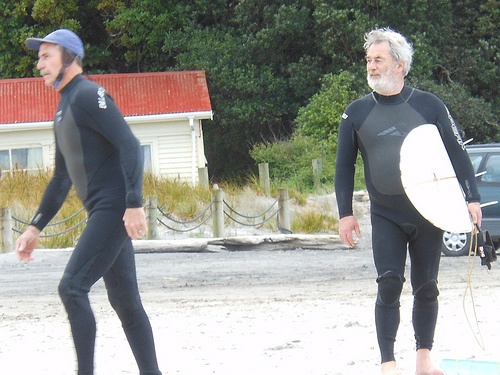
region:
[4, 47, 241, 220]
a white building with a red roof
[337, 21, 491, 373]
a man wearing a black swim suit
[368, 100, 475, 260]
a white surf board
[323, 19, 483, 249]
a man with grey hair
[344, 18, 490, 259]
a man holding a surf board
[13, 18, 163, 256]
a man wearing a ring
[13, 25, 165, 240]
a man wearing a hat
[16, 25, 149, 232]
a man wearing a hat that straps under his chin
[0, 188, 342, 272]
a metal beach fence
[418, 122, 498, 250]
a green vehicle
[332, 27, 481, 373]
Man holding a white surfboard.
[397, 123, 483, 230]
Surfboard under the man's arm.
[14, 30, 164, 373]
Man walking in a black wet suit.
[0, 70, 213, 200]
White house with red roof.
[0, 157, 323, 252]
Fence with chain links.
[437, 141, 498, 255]
Parked car behind the man.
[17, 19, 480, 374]
Two men walking towards the beach.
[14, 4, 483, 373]
Two men wearing wet suits.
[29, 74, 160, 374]
Black long sleeve wet suit.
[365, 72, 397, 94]
Gray beard on man's face.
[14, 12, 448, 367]
Two men holding boards.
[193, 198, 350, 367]
Sand on the ground.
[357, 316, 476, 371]
Man with bare feet.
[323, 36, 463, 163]
Man with white hair.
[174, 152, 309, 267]
Fence in the background.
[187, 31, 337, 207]
Green trees in the background.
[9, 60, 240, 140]
House with red rood.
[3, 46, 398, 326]
White building on the beach.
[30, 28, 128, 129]
Blue hat on man's head.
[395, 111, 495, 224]
Vehicle on the beach.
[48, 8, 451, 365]
two men in black suits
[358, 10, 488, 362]
older man carrying a white surfboard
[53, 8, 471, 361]
two men walking on beach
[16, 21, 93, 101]
man wearing a blue hat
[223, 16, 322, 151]
green leafy trees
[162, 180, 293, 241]
wooden and chain fence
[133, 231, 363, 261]
long piece of dead drift wood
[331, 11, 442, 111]
man with white hair and beard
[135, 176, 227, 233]
tall green beach grass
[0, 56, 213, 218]
white building with red roof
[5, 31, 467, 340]
two men are going surfing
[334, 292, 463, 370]
man with no shoes on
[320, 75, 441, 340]
man in black wet suit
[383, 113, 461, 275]
man holding white surfboard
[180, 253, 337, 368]
sandy road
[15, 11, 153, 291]
man with blue hat on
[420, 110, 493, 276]
car is behind man holding surfboard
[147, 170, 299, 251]
wooden poles with rope barriers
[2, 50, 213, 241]
small house behind man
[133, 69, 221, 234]
small red and white house